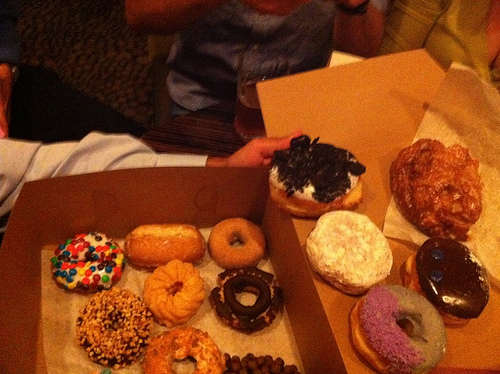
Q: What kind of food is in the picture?
A: Doughnuts.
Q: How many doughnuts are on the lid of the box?
A: 5.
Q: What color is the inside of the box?
A: Brown.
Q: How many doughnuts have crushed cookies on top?
A: 1.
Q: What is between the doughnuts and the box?
A: Paper.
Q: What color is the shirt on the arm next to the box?
A: White.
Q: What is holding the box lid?
A: A hand.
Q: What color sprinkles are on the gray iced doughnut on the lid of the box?
A: Purple.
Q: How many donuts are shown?
A: Thirteen.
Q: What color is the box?
A: Brown.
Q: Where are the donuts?
A: Box.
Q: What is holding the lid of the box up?
A: Hand.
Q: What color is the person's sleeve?
A: White.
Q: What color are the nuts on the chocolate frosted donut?
A: Brown.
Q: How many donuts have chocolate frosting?
A: Four.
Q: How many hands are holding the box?
A: One.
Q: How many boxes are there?
A: One.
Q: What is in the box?
A: Doughnuts.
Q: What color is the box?
A: Brown.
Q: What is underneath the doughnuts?
A: Wax paper.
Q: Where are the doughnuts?
A: In the box.